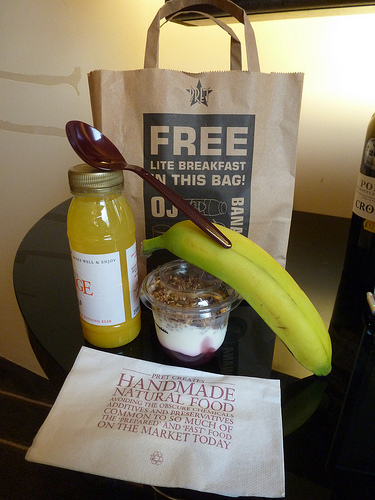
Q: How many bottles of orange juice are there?
A: 1.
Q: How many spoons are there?
A: 1.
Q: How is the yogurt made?
A: By hand.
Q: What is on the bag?
A: Advertisement.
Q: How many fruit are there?
A: 1.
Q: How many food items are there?
A: 3.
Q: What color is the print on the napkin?
A: Red.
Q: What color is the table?
A: Black.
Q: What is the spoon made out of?
A: Plastic.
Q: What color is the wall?
A: Yellow.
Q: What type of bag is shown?
A: Paper sack.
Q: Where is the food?
A: Counter.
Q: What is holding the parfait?
A: Plastic container.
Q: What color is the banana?
A: Yellow and green.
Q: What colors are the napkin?
A: White with red words.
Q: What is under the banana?
A: Yogurt cup.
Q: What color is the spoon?
A: Maroon.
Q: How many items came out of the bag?
A: Five.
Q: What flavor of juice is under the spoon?
A: Orange.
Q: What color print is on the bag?
A: Black.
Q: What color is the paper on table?
A: White.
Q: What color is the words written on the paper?
A: Red.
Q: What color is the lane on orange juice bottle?
A: White.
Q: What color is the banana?
A: Yellow.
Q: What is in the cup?
A: Yogurt with granola.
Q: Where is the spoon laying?
A: On the juice.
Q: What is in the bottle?
A: Juice.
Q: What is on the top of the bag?
A: Star.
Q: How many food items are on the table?
A: 3.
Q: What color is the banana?
A: Yellow.